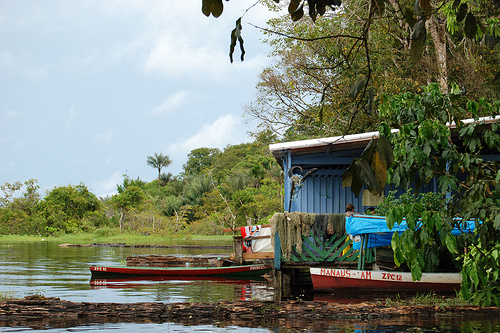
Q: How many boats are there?
A: Two.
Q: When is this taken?
A: During the day time.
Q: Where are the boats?
A: On the water.